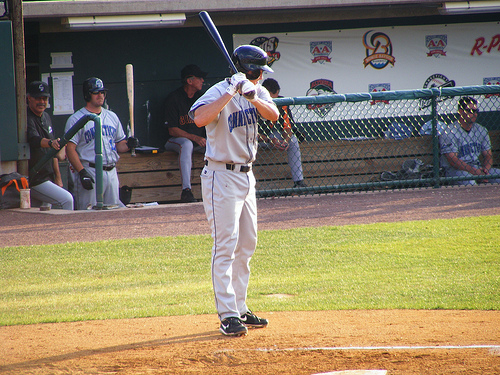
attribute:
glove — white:
[192, 40, 280, 343]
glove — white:
[239, 80, 256, 104]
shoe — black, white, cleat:
[214, 311, 271, 338]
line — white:
[224, 342, 499, 358]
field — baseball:
[11, 172, 497, 372]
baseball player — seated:
[437, 92, 497, 181]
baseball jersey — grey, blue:
[189, 78, 275, 165]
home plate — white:
[309, 362, 384, 373]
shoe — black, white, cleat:
[213, 301, 277, 336]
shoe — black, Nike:
[238, 306, 268, 329]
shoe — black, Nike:
[215, 311, 251, 338]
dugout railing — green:
[252, 87, 497, 198]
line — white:
[301, 337, 434, 359]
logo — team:
[356, 26, 398, 75]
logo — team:
[303, 33, 338, 73]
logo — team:
[311, 77, 338, 119]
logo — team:
[420, 26, 456, 61]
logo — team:
[468, 31, 498, 62]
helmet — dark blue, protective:
[228, 45, 273, 72]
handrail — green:
[37, 111, 108, 211]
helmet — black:
[235, 43, 272, 71]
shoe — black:
[218, 317, 248, 337]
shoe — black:
[241, 312, 269, 328]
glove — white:
[240, 80, 258, 100]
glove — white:
[225, 68, 247, 95]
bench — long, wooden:
[123, 131, 433, 190]